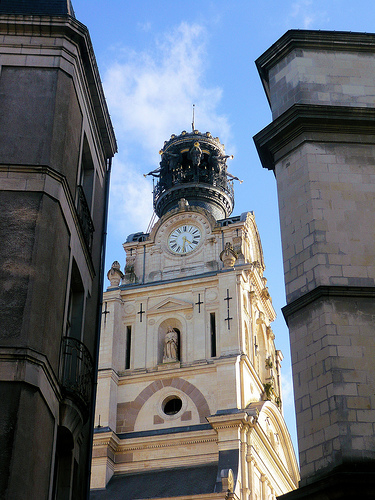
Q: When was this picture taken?
A: During the day.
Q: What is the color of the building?
A: Ivory.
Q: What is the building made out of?
A: Marble.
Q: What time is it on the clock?
A: 4:30.